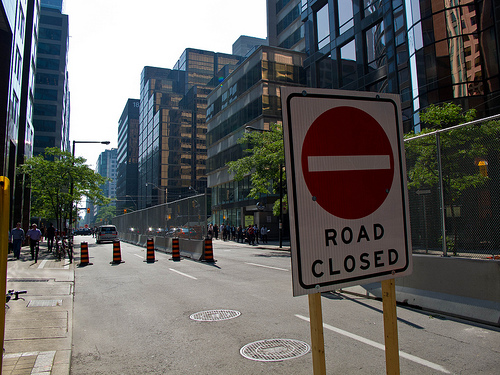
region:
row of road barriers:
[48, 200, 255, 291]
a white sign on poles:
[258, 56, 431, 371]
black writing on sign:
[292, 203, 414, 284]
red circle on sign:
[288, 98, 410, 225]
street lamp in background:
[51, 100, 145, 293]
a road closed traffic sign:
[282, 87, 417, 297]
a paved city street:
[67, 229, 497, 372]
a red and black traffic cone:
[78, 242, 90, 264]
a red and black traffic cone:
[110, 238, 125, 265]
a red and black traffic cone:
[142, 237, 159, 264]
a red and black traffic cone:
[169, 236, 182, 260]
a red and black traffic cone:
[202, 233, 217, 263]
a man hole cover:
[191, 307, 241, 322]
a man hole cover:
[238, 337, 309, 364]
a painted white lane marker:
[166, 265, 198, 281]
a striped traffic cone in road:
[69, 231, 94, 274]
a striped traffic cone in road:
[111, 230, 127, 272]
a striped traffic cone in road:
[134, 221, 163, 276]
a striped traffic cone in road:
[164, 239, 187, 269]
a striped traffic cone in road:
[192, 236, 217, 268]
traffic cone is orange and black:
[110, 239, 130, 274]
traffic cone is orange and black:
[166, 229, 186, 259]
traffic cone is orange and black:
[194, 240, 215, 272]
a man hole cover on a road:
[192, 306, 244, 325]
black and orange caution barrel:
[200, 235, 215, 265]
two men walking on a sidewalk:
[11, 221, 43, 257]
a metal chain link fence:
[120, 189, 210, 229]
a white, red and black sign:
[288, 87, 408, 295]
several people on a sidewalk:
[214, 220, 257, 241]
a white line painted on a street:
[165, 266, 199, 283]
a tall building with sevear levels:
[137, 46, 212, 200]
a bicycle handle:
[5, 286, 25, 311]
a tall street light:
[63, 135, 114, 246]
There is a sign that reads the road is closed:
[263, 76, 433, 373]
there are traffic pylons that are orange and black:
[75, 235, 215, 263]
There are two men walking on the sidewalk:
[12, 218, 42, 260]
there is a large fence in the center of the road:
[108, 194, 205, 256]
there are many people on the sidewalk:
[206, 216, 269, 246]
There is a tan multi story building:
[190, 37, 304, 234]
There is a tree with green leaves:
[16, 144, 113, 254]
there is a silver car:
[88, 220, 120, 243]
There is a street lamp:
[63, 133, 111, 258]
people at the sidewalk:
[174, 216, 271, 248]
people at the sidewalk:
[177, 210, 262, 242]